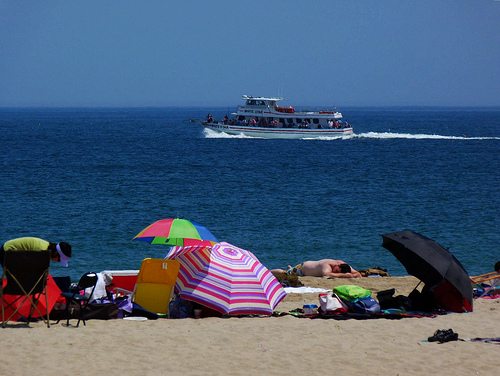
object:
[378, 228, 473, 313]
umbrella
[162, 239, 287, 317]
umbrella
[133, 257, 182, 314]
chair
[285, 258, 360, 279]
man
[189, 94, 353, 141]
boat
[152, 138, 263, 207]
ocean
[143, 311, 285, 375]
beach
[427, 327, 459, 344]
shoes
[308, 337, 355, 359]
sand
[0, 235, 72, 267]
person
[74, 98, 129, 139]
water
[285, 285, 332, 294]
towel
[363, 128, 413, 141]
waves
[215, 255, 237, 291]
stripes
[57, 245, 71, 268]
cap